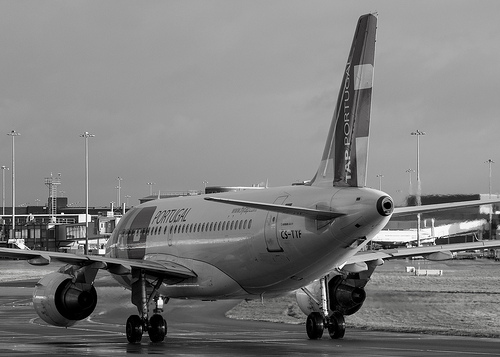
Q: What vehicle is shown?
A: Airplane.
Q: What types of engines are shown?
A: Turbine.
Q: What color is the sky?
A: Grey.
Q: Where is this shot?
A: Runway.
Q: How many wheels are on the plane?
A: 4.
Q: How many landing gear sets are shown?
A: 2.